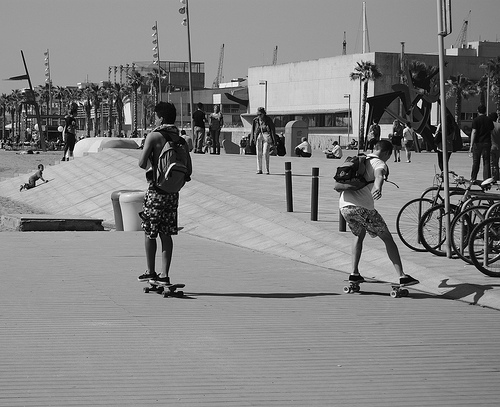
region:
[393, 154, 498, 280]
Four bicycles side by side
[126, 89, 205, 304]
Man riding a skateboard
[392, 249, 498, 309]
Shadow of person riding skateboard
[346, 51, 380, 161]
Palm tree next to building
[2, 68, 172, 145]
Multiple palm trees running alongside of building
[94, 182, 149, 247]
Two trash cans next to the street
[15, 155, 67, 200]
Child crawling on the ground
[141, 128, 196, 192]
Back pack on back of skateboarder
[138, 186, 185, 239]
Patterned shorts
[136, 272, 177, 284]
Black and white tennis shoes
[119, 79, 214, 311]
Boy skateboarding ahead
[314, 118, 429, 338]
Boy trying to do a trick on a skateboard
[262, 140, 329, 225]
two black road poles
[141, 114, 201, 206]
Black and white backpack on skateboarder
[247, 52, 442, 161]
Large white building on the side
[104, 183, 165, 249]
Two grey and white trash cans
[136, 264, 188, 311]
Black skateboard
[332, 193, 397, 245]
Black and white shorts on skateboarder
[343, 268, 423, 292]
Black and white sneakers on skateboarder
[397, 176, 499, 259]
Row of bikes on the sidewalk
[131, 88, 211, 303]
the man is skateboarding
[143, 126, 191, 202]
man wearing a backpack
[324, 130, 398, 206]
man wearing a backpack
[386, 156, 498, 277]
bicycles on the sidewalk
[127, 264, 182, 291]
man's shoes are black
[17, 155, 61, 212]
person on the ground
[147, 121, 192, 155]
backpack has black straps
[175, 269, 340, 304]
shadow of man on ground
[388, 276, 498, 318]
shadow of man on ground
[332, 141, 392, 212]
man's shirt is white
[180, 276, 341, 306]
shadow of skateboarder on left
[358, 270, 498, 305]
shadow of skateboarder on right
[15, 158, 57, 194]
child crawling up concrete slope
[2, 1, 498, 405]
black and white photo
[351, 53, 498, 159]
palm trees onside of front building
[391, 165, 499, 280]
bikes parked on racks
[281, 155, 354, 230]
black poles next to slope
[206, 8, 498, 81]
utility towers behind buildings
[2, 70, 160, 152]
row of palm trees along back building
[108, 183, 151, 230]
white round structure in front of slope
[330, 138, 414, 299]
Young person with a backpack, and practicing skateboard moves.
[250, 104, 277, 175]
A woman looking down at the sidewalk, possibly searching for something she may have lost.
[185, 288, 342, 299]
Thin, dark shadow of the taller boy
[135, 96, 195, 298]
Taller boy with a backpack, contemplating his next move with his skateboard.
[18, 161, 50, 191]
Young boy creating his own playground by crawling up the slanted brick walkway/skateboard ramp.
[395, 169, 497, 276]
Numerous bicycles parked in a bike rack.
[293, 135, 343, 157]
Two people sitting in the warm sunlight, reading a book or just enjoying the day.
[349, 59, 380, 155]
Palm tree planted at the corner of a building.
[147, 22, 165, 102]
Street lights or aerial lights to illuminate the skate board area.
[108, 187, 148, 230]
Trash cans at the edge of the play area.